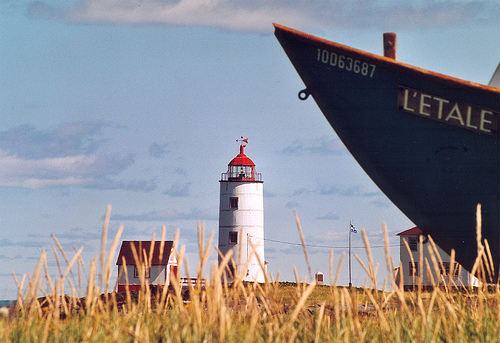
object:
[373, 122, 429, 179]
wall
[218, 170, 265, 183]
railing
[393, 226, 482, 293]
house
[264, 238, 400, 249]
power line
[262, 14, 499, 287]
boat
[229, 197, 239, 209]
window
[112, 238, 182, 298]
house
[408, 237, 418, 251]
window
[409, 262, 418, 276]
window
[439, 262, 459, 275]
window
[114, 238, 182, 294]
building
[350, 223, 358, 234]
flag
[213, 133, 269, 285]
building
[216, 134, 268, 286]
light house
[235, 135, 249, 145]
weather vane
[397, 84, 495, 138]
paint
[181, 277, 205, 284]
fence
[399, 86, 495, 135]
text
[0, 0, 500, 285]
sky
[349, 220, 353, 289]
flagpole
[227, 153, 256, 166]
roof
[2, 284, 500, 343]
grass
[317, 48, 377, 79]
number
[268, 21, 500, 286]
bow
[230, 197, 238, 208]
windows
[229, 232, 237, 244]
windows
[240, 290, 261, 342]
plants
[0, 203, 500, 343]
field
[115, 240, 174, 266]
roof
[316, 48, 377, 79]
serial number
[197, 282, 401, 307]
hill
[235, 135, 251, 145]
weather vein